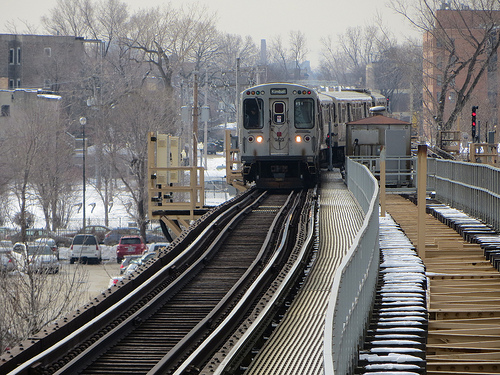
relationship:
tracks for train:
[122, 199, 336, 318] [201, 60, 422, 177]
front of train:
[230, 53, 333, 175] [201, 60, 422, 177]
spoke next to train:
[217, 105, 240, 174] [201, 60, 422, 177]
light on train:
[225, 128, 279, 182] [201, 60, 422, 177]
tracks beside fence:
[122, 199, 336, 318] [332, 124, 440, 349]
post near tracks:
[160, 101, 219, 209] [122, 199, 336, 318]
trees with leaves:
[28, 93, 113, 168] [35, 103, 89, 164]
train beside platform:
[201, 60, 422, 177] [347, 153, 421, 288]